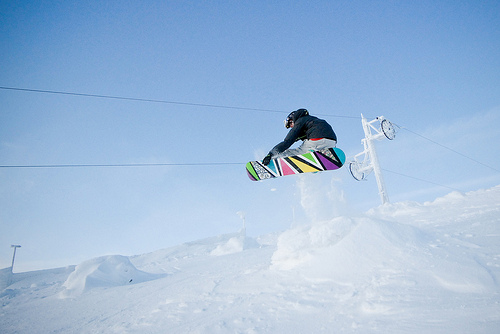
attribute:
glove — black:
[261, 156, 271, 167]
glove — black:
[308, 170, 318, 174]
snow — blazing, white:
[2, 186, 496, 331]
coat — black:
[264, 116, 336, 159]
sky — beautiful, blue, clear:
[1, 1, 497, 272]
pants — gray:
[272, 135, 337, 161]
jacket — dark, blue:
[268, 117, 338, 153]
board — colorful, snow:
[246, 149, 345, 180]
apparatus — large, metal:
[348, 113, 396, 207]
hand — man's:
[263, 152, 272, 166]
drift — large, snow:
[63, 252, 183, 302]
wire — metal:
[11, 148, 232, 181]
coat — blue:
[262, 120, 349, 146]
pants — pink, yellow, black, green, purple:
[240, 157, 366, 179]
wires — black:
[8, 80, 233, 194]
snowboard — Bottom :
[244, 142, 344, 182]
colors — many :
[294, 151, 335, 169]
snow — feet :
[237, 228, 423, 330]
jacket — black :
[260, 116, 342, 173]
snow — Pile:
[274, 213, 420, 279]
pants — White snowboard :
[293, 136, 342, 155]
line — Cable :
[0, 81, 252, 195]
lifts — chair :
[5, 89, 238, 191]